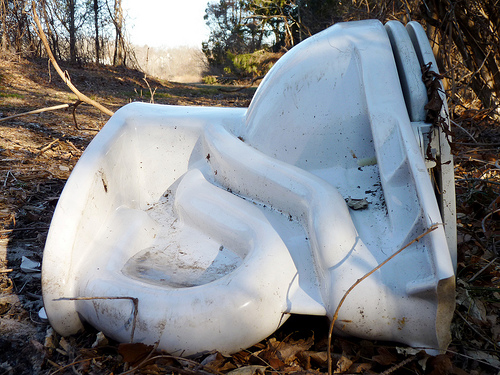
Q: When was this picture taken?
A: During the day.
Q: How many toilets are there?
A: One.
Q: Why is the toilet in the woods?
A: It's broken.